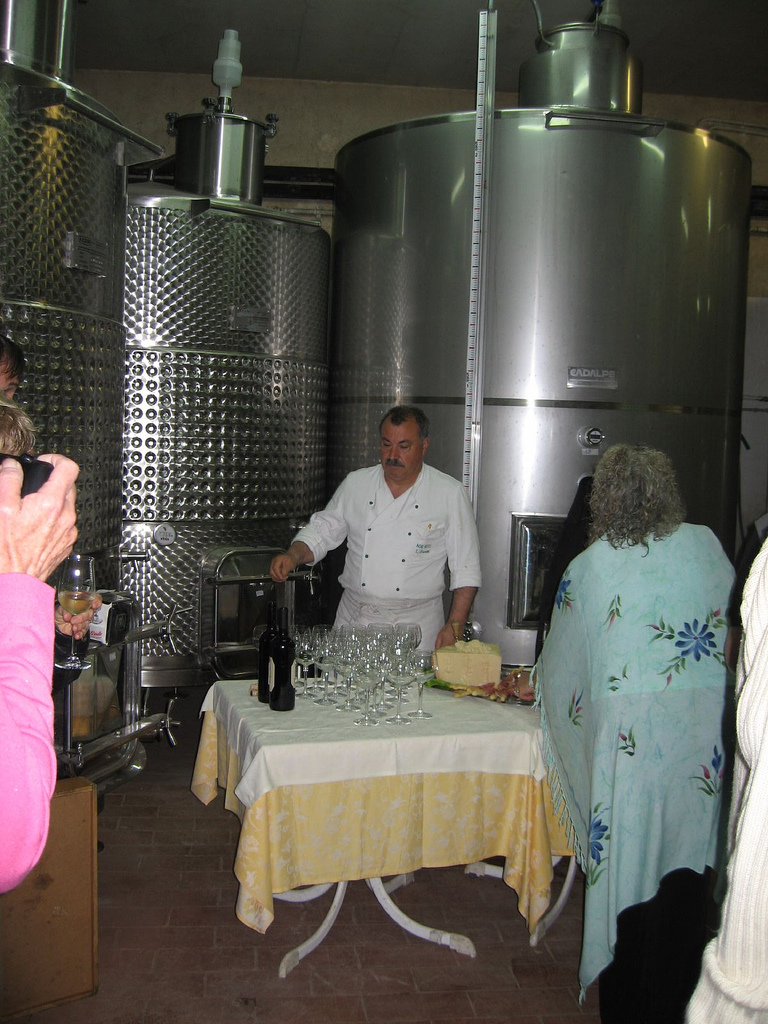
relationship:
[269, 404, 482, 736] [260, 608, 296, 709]
man pointing to wine bottle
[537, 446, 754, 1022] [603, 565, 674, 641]
woman wearing a caftan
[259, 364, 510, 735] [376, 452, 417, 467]
man has moustache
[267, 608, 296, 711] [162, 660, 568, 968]
bottle on table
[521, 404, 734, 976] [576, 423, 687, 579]
woman has hair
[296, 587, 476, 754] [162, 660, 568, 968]
glasses on table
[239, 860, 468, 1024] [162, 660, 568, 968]
legs of table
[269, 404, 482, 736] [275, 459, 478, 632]
man in coat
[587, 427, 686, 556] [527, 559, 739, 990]
hair over shaw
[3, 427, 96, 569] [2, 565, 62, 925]
hand above sleeve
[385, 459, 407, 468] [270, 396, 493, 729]
moustache on man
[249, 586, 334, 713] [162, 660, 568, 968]
bottle on table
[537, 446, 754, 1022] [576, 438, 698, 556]
woman has hair